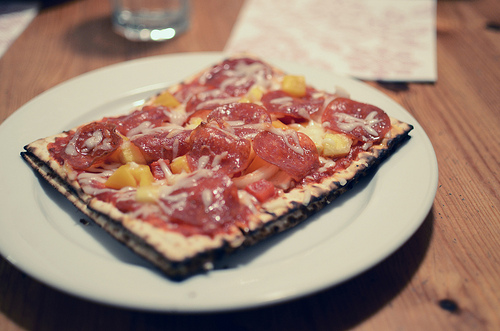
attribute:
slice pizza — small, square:
[21, 51, 416, 288]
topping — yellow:
[109, 154, 154, 184]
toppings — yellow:
[46, 53, 393, 241]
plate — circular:
[96, 75, 132, 100]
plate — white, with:
[0, 54, 436, 314]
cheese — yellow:
[106, 160, 155, 190]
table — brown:
[38, 5, 498, 321]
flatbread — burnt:
[19, 43, 417, 289]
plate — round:
[70, 17, 470, 329]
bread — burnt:
[340, 133, 400, 192]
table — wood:
[448, 187, 492, 267]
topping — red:
[185, 120, 253, 175]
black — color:
[291, 200, 297, 209]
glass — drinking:
[106, 0, 193, 44]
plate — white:
[10, 40, 432, 296]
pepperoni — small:
[60, 128, 121, 173]